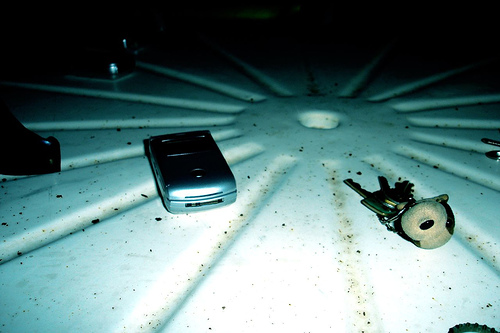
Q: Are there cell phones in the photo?
A: Yes, there is a cell phone.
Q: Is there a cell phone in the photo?
A: Yes, there is a cell phone.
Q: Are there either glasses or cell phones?
A: Yes, there is a cell phone.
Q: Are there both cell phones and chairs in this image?
A: No, there is a cell phone but no chairs.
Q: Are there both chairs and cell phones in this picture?
A: No, there is a cell phone but no chairs.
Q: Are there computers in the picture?
A: No, there are no computers.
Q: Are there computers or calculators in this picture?
A: No, there are no computers or calculators.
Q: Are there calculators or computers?
A: No, there are no computers or calculators.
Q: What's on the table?
A: The cell phone is on the table.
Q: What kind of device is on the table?
A: The device is a cell phone.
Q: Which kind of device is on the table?
A: The device is a cell phone.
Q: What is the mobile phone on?
A: The mobile phone is on the table.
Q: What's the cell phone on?
A: The mobile phone is on the table.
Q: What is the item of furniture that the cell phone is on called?
A: The piece of furniture is a table.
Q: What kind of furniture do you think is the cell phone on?
A: The cell phone is on the table.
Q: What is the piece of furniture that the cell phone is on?
A: The piece of furniture is a table.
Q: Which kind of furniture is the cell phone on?
A: The cell phone is on the table.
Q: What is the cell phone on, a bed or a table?
A: The cell phone is on a table.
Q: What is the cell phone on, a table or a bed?
A: The cell phone is on a table.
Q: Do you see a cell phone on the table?
A: Yes, there is a cell phone on the table.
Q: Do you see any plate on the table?
A: No, there is a cell phone on the table.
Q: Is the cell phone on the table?
A: Yes, the cell phone is on the table.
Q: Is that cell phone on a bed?
A: No, the cell phone is on the table.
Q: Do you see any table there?
A: Yes, there is a table.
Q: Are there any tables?
A: Yes, there is a table.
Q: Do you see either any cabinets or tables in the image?
A: Yes, there is a table.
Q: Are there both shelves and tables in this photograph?
A: No, there is a table but no shelves.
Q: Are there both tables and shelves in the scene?
A: No, there is a table but no shelves.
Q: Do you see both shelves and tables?
A: No, there is a table but no shelves.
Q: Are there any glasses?
A: No, there are no glasses.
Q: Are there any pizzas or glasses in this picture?
A: No, there are no glasses or pizzas.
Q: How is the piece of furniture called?
A: The piece of furniture is a table.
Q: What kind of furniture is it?
A: The piece of furniture is a table.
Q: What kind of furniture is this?
A: That is a table.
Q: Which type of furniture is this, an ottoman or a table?
A: That is a table.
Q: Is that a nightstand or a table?
A: That is a table.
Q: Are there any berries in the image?
A: No, there are no berries.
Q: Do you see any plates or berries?
A: No, there are no berries or plates.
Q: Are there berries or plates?
A: No, there are no berries or plates.